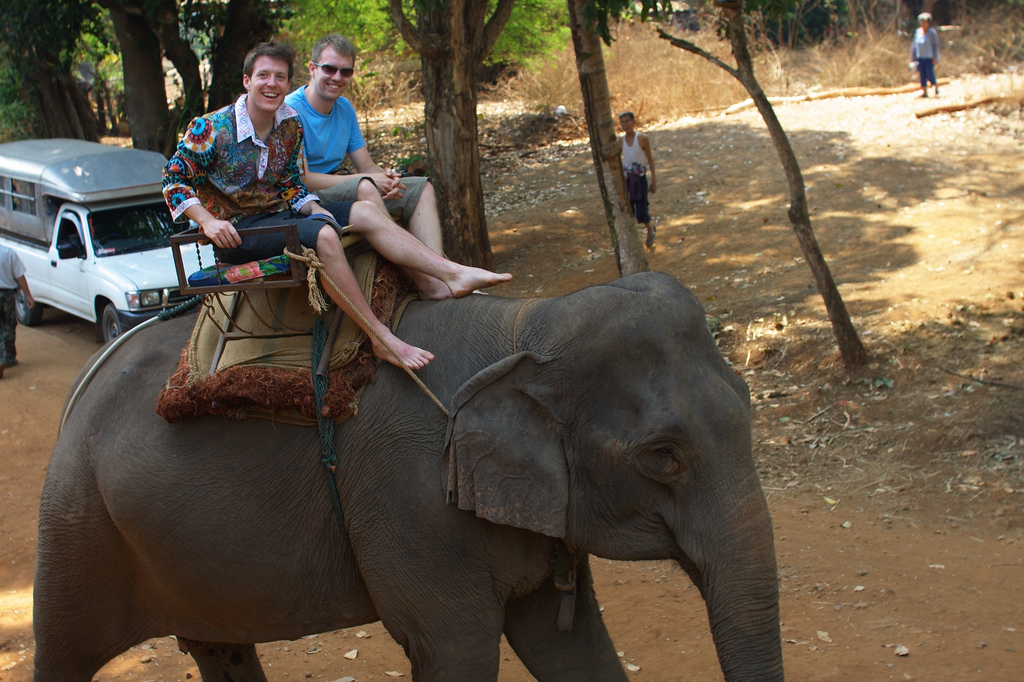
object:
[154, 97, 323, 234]
shirt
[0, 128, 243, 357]
truck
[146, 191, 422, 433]
seat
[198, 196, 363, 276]
shorts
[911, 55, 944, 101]
pants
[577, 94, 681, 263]
men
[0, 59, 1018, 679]
ground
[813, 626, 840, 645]
leaf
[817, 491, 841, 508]
leaf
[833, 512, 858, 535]
leaf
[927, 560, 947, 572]
leaf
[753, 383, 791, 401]
leaf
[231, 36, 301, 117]
head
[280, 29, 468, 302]
man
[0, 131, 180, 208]
camper shell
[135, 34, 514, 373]
man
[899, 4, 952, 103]
woman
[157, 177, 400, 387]
fabric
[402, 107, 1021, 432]
shadow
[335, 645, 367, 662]
leaf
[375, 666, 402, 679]
leaf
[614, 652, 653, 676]
leaf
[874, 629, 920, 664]
leaf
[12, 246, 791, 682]
elephant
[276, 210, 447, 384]
legs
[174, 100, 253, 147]
shoulders